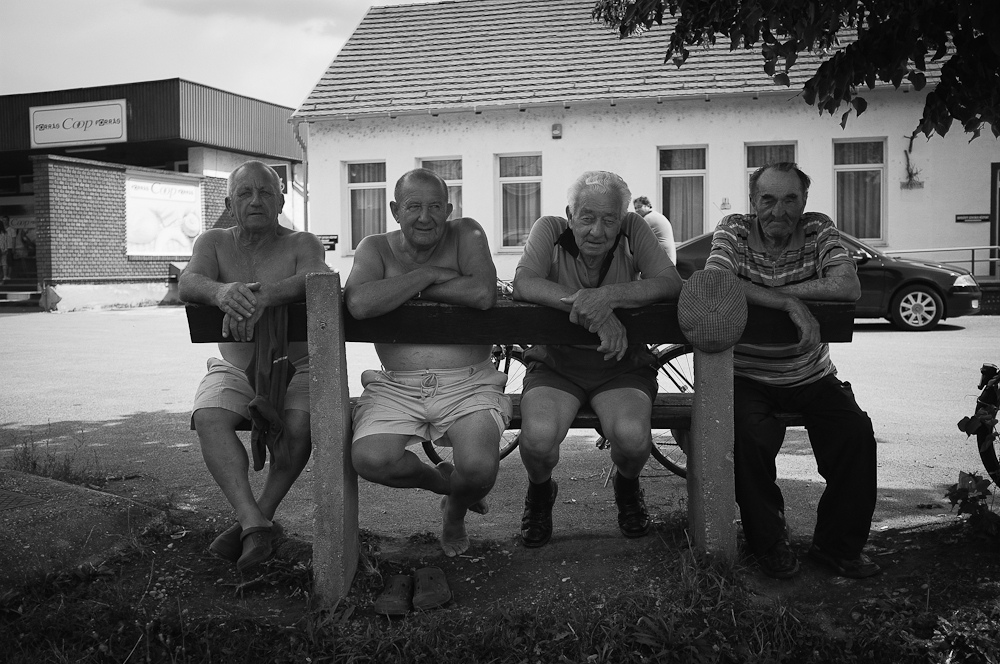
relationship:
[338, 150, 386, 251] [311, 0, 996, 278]
window on building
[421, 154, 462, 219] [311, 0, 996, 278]
window on building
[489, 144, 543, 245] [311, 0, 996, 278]
window on building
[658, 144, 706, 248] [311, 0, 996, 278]
window on building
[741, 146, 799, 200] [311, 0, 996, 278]
window on building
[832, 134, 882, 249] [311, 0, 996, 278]
window on building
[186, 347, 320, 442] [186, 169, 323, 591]
shorts on man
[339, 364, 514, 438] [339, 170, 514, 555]
shorts on man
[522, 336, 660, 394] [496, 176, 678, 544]
shorts on man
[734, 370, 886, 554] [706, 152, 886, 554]
pants on a man